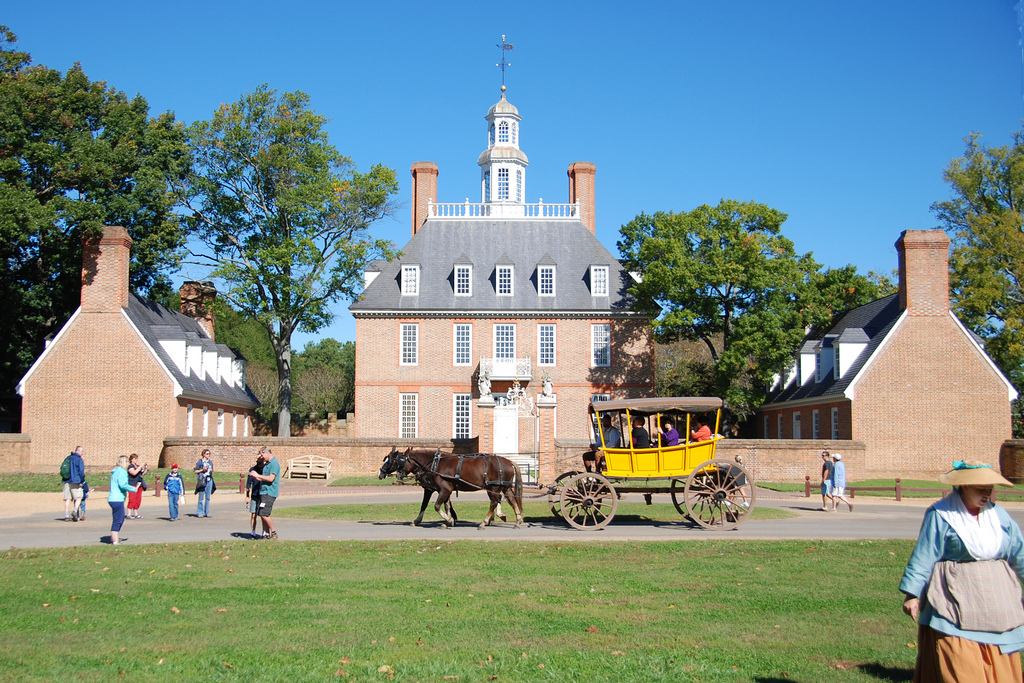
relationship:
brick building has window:
[328, 62, 660, 480] [401, 321, 418, 363]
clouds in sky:
[584, 131, 714, 212] [529, 20, 1000, 123]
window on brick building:
[537, 265, 556, 297] [343, 26, 661, 488]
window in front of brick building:
[534, 259, 577, 292] [343, 26, 661, 488]